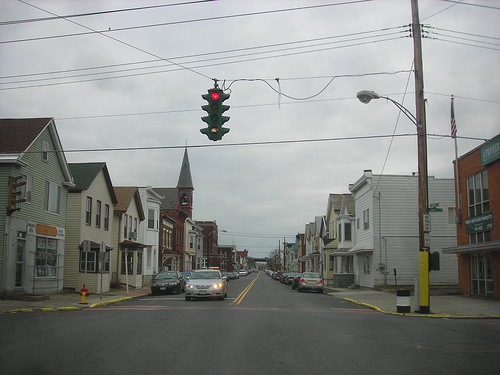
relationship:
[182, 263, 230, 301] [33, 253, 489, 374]
car on road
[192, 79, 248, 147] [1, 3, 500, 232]
light below sky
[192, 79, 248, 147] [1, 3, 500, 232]
light under sky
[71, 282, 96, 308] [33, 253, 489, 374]
hydrant near road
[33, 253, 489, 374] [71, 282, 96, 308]
road near hydrant